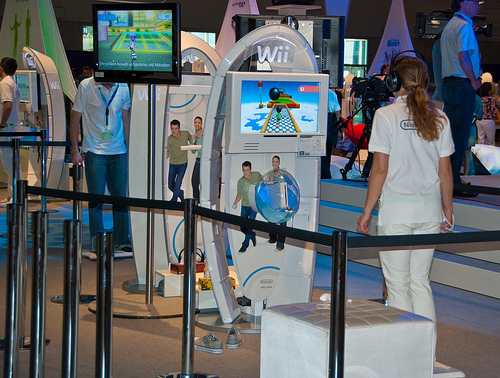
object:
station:
[283, 173, 445, 281]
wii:
[255, 182, 290, 213]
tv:
[15, 130, 31, 163]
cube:
[305, 223, 499, 307]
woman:
[355, 50, 458, 371]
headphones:
[384, 50, 432, 95]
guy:
[66, 74, 138, 254]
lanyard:
[95, 79, 121, 131]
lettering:
[256, 43, 291, 65]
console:
[190, 24, 331, 334]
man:
[0, 56, 28, 206]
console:
[127, 28, 252, 295]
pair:
[3, 201, 51, 377]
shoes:
[0, 197, 18, 210]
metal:
[92, 230, 112, 377]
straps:
[24, 185, 186, 211]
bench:
[258, 298, 434, 376]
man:
[434, 0, 486, 199]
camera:
[324, 73, 402, 185]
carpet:
[118, 318, 183, 357]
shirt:
[366, 94, 461, 229]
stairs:
[318, 179, 499, 302]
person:
[63, 214, 117, 377]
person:
[203, 24, 467, 377]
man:
[317, 71, 343, 180]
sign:
[298, 132, 327, 158]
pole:
[92, 207, 116, 378]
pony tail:
[388, 56, 449, 145]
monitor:
[91, 0, 182, 88]